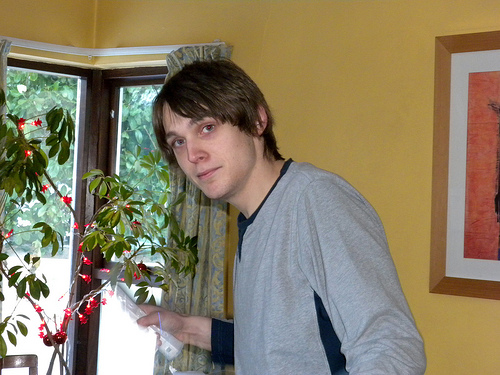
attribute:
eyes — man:
[175, 130, 215, 143]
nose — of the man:
[192, 138, 195, 162]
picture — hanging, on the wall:
[463, 139, 497, 256]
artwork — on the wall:
[431, 145, 491, 196]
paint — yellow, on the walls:
[313, 100, 329, 120]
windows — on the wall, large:
[35, 150, 143, 186]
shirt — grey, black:
[237, 174, 407, 370]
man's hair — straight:
[151, 40, 282, 173]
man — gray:
[115, 50, 418, 360]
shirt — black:
[210, 161, 445, 361]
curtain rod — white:
[9, 35, 229, 60]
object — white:
[107, 277, 183, 358]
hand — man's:
[128, 299, 188, 350]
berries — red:
[62, 295, 101, 327]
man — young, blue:
[136, 52, 425, 374]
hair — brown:
[150, 56, 284, 181]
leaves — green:
[0, 108, 197, 348]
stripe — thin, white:
[154, 312, 163, 329]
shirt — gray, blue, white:
[207, 154, 430, 374]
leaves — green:
[40, 102, 77, 163]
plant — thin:
[1, 83, 201, 368]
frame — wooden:
[425, 30, 462, 298]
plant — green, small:
[6, 102, 201, 373]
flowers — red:
[76, 252, 91, 283]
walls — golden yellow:
[3, 1, 493, 373]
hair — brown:
[170, 58, 252, 111]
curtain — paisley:
[153, 43, 227, 373]